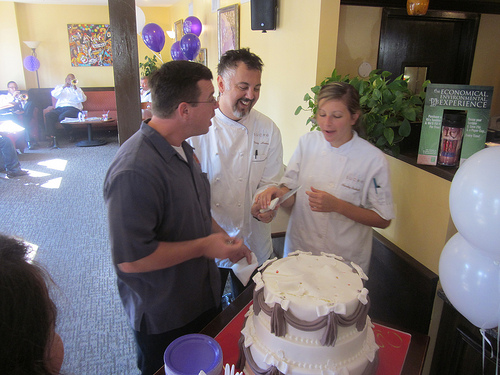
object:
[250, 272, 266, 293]
bow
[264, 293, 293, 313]
bow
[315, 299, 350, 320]
bow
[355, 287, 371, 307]
bow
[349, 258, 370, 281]
bow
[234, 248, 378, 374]
cake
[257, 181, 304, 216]
knife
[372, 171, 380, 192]
pen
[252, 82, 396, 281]
woman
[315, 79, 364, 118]
hair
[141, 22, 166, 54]
balloon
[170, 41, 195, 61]
balloon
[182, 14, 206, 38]
balloon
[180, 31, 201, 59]
balloon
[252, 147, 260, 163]
pen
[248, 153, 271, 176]
pocket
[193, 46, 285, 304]
man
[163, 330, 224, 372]
plates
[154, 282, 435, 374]
table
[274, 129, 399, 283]
shirt